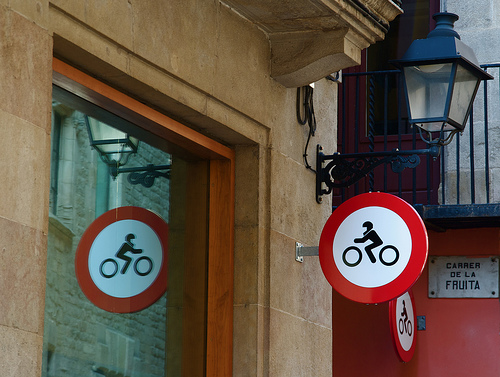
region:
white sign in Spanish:
[425, 248, 497, 301]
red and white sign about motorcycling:
[318, 189, 428, 304]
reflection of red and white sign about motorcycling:
[75, 204, 180, 314]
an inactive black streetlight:
[385, 7, 495, 153]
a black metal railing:
[335, 57, 499, 226]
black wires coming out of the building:
[290, 58, 325, 184]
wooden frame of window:
[33, 40, 244, 374]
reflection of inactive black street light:
[77, 99, 147, 191]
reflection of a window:
[40, 90, 82, 242]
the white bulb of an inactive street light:
[415, 55, 447, 78]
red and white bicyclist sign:
[318, 192, 428, 302]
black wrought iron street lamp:
[407, 12, 473, 162]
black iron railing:
[456, 165, 495, 214]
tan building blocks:
[231, 297, 335, 374]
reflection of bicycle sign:
[71, 197, 170, 317]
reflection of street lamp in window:
[78, 112, 198, 190]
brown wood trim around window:
[130, 98, 269, 153]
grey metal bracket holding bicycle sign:
[408, 310, 430, 338]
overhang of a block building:
[260, 0, 408, 90]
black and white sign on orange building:
[424, 250, 499, 325]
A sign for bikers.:
[309, 205, 384, 282]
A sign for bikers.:
[253, 136, 379, 275]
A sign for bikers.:
[324, 206, 432, 315]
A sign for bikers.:
[305, 84, 450, 316]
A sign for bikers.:
[335, 225, 398, 320]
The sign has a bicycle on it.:
[327, 193, 429, 299]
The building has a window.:
[69, 79, 244, 364]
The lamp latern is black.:
[396, 43, 478, 165]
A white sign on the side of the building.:
[418, 244, 498, 305]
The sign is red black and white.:
[316, 203, 439, 295]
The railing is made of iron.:
[351, 67, 486, 207]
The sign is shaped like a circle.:
[317, 188, 440, 293]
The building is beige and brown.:
[262, 136, 332, 374]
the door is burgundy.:
[361, 58, 446, 221]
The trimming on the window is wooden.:
[67, 83, 232, 173]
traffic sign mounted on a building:
[295, 182, 442, 307]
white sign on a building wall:
[419, 241, 498, 311]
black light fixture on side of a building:
[394, 3, 486, 158]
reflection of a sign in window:
[68, 197, 182, 319]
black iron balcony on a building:
[431, 147, 498, 225]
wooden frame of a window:
[202, 142, 241, 374]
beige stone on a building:
[247, 142, 295, 374]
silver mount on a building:
[292, 238, 318, 269]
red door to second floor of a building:
[344, 73, 413, 195]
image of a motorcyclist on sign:
[334, 218, 405, 275]